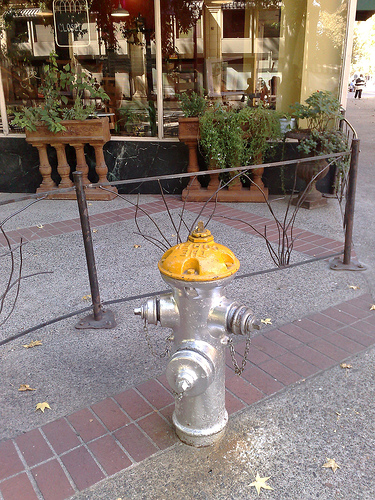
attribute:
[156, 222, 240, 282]
lid — yellow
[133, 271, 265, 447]
hydrant — silver, shiny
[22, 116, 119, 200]
holder — brown, brass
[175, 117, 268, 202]
holder — brown, brass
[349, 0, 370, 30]
awning — green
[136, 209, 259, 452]
hydrant — silver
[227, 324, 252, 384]
chain — metallic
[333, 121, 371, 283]
post — black, iron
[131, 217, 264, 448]
fire hydrant — silver, yellow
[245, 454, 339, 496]
leaves — yellow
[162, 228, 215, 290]
cover — Gold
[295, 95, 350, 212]
planter — decorative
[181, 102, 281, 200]
planter — decorative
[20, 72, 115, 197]
planter — decorative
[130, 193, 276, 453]
fire hydrant — yellow, silver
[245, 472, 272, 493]
leaf — star shaped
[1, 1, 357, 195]
building — large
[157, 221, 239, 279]
top — yellow